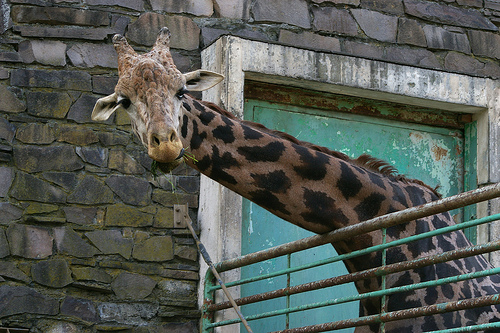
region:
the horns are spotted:
[100, 27, 195, 60]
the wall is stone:
[26, 95, 192, 330]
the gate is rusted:
[215, 231, 486, 316]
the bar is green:
[283, 237, 420, 268]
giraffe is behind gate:
[135, 55, 465, 300]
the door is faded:
[255, 110, 439, 256]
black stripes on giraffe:
[291, 145, 338, 177]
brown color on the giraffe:
[290, 174, 358, 211]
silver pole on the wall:
[158, 194, 225, 291]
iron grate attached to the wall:
[196, 231, 431, 331]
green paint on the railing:
[240, 260, 347, 276]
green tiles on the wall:
[94, 200, 159, 230]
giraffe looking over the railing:
[62, 26, 446, 262]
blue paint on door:
[298, 115, 365, 135]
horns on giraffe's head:
[95, 19, 187, 62]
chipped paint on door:
[246, 225, 279, 240]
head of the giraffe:
[81, 27, 246, 191]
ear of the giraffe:
[174, 50, 234, 110]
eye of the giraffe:
[163, 71, 194, 112]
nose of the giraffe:
[133, 106, 190, 166]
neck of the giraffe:
[191, 90, 415, 256]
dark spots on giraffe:
[191, 124, 373, 249]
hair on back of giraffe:
[273, 128, 409, 182]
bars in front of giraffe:
[232, 210, 385, 325]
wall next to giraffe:
[26, 146, 123, 257]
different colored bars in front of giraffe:
[220, 215, 369, 328]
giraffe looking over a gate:
[93, 37, 493, 321]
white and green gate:
[199, 193, 499, 330]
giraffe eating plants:
[96, 34, 488, 324]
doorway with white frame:
[198, 38, 497, 322]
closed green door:
[248, 96, 475, 331]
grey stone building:
[9, 5, 499, 322]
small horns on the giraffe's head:
[108, 17, 173, 59]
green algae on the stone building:
[10, 82, 205, 291]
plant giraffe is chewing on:
[136, 142, 198, 179]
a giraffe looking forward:
[87, 22, 497, 330]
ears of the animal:
[85, 62, 225, 122]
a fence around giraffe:
[195, 175, 496, 330]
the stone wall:
[1, 5, 496, 330]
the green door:
[240, 76, 485, 326]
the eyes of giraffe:
[115, 85, 185, 110]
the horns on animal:
[106, 21, 168, 51]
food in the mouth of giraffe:
[141, 141, 196, 181]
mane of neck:
[192, 96, 397, 181]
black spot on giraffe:
[196, 110, 214, 123]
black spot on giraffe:
[189, 118, 206, 153]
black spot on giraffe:
[210, 124, 235, 144]